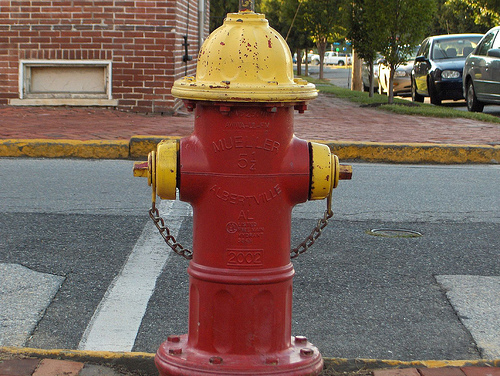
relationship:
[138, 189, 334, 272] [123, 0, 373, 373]
chains on fire hydrant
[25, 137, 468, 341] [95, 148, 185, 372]
road has markings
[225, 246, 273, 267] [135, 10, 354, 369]
"2002" written fire hydrant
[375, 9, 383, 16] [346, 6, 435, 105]
leaves on tree